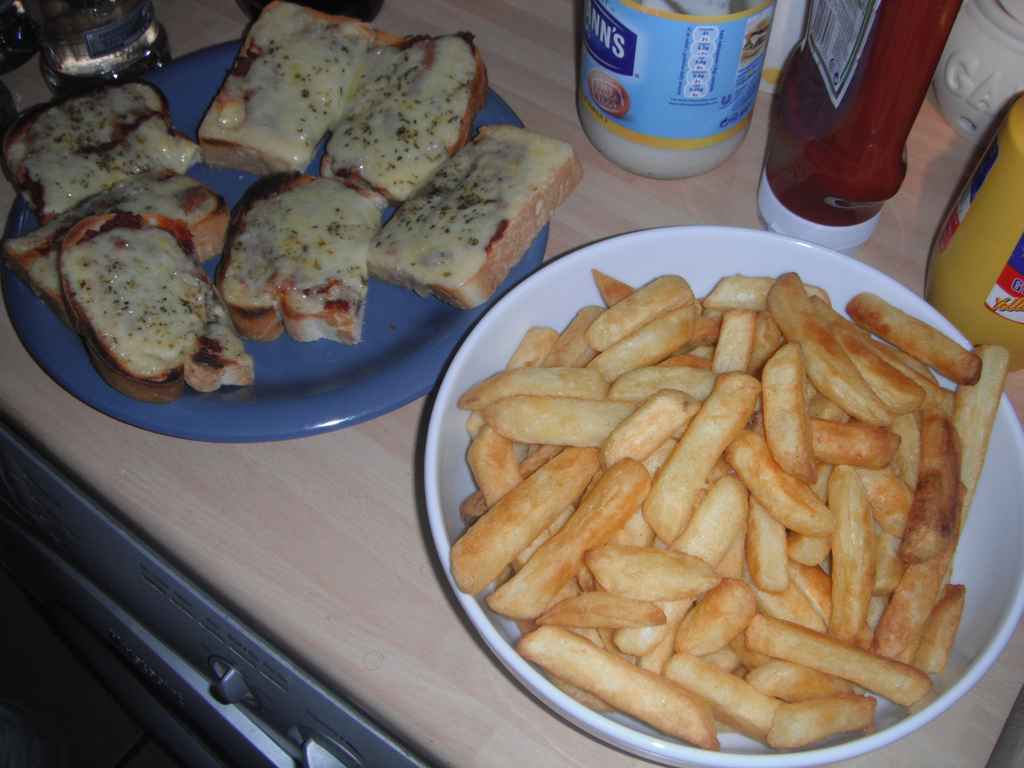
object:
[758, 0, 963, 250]
ketchup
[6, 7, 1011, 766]
food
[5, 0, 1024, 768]
plate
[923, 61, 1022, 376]
mustard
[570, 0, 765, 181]
mayo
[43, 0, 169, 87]
glass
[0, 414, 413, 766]
oven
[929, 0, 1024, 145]
jar